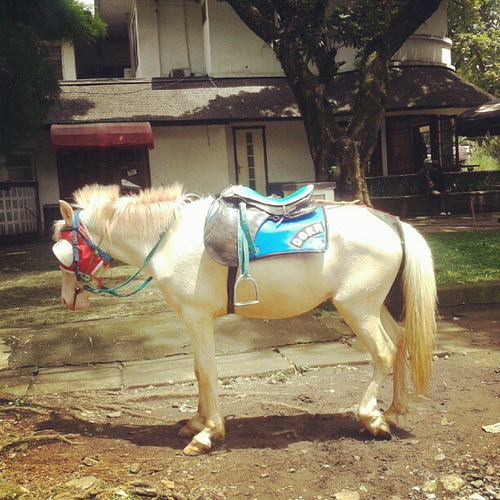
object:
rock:
[441, 474, 462, 493]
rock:
[471, 475, 483, 488]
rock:
[435, 451, 444, 461]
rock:
[332, 488, 361, 498]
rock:
[131, 460, 139, 472]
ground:
[5, 236, 497, 498]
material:
[59, 221, 110, 276]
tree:
[3, 1, 107, 159]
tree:
[446, 0, 498, 101]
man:
[416, 158, 446, 215]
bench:
[366, 171, 497, 221]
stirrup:
[232, 272, 259, 307]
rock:
[420, 478, 438, 497]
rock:
[434, 460, 486, 497]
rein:
[72, 211, 179, 291]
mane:
[75, 182, 197, 235]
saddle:
[202, 175, 332, 266]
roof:
[55, 58, 497, 143]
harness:
[71, 208, 180, 298]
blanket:
[203, 197, 328, 266]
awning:
[47, 120, 153, 149]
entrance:
[58, 149, 149, 187]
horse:
[52, 180, 439, 457]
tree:
[230, 8, 410, 225]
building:
[0, 0, 500, 245]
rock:
[449, 460, 487, 489]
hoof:
[179, 423, 199, 438]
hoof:
[183, 439, 212, 455]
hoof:
[378, 420, 392, 440]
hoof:
[384, 415, 397, 428]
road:
[81, 451, 100, 469]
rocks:
[277, 339, 356, 373]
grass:
[429, 224, 498, 282]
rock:
[482, 423, 500, 440]